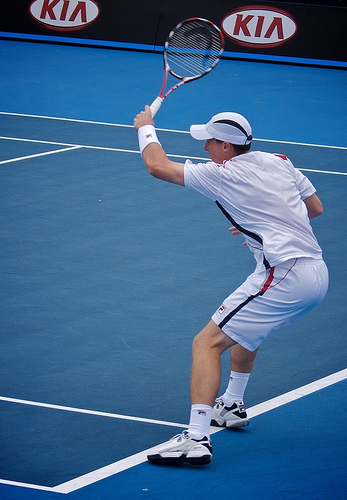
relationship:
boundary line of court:
[1, 113, 347, 175] [1, 39, 346, 499]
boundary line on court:
[1, 113, 347, 175] [1, 39, 346, 499]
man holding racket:
[134, 107, 329, 465] [140, 17, 224, 119]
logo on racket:
[184, 26, 212, 69] [140, 17, 224, 119]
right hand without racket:
[227, 227, 248, 246] [140, 17, 224, 119]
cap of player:
[189, 112, 253, 146] [134, 107, 329, 465]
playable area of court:
[2, 137, 346, 494] [1, 39, 346, 499]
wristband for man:
[136, 125, 162, 157] [134, 107, 329, 465]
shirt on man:
[182, 150, 323, 273] [134, 107, 329, 465]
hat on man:
[189, 112, 253, 146] [134, 107, 329, 465]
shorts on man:
[212, 258, 329, 353] [134, 107, 329, 465]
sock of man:
[189, 403, 210, 441] [134, 107, 329, 465]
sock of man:
[225, 370, 249, 405] [134, 107, 329, 465]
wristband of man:
[136, 125, 162, 157] [134, 107, 329, 465]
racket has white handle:
[140, 17, 224, 119] [149, 96, 164, 121]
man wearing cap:
[134, 107, 329, 465] [189, 112, 253, 146]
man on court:
[134, 107, 329, 465] [1, 39, 346, 499]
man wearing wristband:
[134, 107, 329, 465] [136, 125, 162, 157]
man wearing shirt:
[134, 107, 329, 465] [182, 150, 323, 273]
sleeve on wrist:
[136, 125, 162, 157] [136, 128, 158, 133]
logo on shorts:
[217, 304, 227, 315] [212, 258, 329, 353]